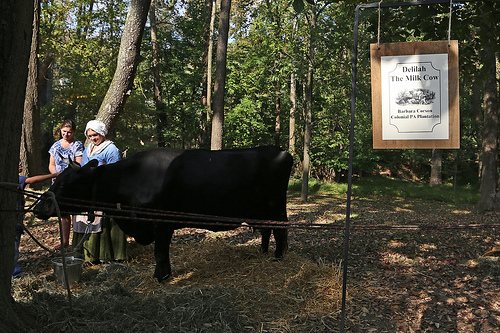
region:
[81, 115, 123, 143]
Person wearing white hat.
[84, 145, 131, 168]
Person wearing blue shirt.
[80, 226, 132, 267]
Person wearing green skirt.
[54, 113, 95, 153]
Person has brown hair.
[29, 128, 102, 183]
Person wearing blue and white shirt.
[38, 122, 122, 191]
People standing next to large cow.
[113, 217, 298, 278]
Cow standing in hay area.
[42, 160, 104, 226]
Cow has black head.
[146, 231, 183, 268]
Cow has black legs.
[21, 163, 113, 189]
Person touching black cow.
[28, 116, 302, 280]
two people looking at a cow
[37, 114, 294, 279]
two women looking at a cow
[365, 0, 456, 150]
a wooden sign hanging from a metal bar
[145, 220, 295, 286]
the four legs of a cow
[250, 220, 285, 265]
the rear legs of a cow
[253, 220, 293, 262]
the back legs of a cow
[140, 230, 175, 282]
the front legs of a cow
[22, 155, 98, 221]
the head of a cow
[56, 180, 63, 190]
the eye of a cow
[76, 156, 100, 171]
the ear of a cow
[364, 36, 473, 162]
A wooden sign on a pole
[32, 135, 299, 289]
a black cow in woods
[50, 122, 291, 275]
a couple of woman standing by a cow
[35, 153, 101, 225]
a cows black head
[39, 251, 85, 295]
a metal pail on the ground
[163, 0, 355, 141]
leafy green trees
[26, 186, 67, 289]
a rope on the cow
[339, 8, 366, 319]
a metal pipe pole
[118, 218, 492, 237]
a tieing rope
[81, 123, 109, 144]
a bonnet on a head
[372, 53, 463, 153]
a sign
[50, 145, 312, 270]
a cow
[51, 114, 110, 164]
two women standing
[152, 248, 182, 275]
front legs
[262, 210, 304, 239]
the ropes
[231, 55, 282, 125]
the leaves on the tree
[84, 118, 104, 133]
a hat on the women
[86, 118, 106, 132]
a white hat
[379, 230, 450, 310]
the dirt is brown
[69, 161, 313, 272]
the cow is black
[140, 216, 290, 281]
the legs of a cow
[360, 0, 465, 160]
a wooden sign hanging from a metal pole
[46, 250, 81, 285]
a shiny metal bucket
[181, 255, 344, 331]
a pile of hay on the ground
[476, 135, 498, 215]
the trunk of a tree